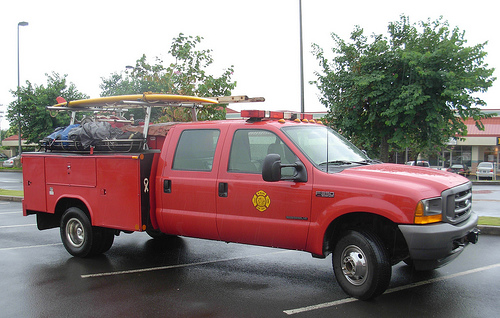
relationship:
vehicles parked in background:
[447, 156, 499, 178] [404, 153, 498, 174]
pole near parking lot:
[12, 16, 34, 143] [7, 172, 498, 317]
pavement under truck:
[1, 240, 499, 313] [12, 94, 486, 306]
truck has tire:
[12, 94, 486, 306] [328, 227, 399, 305]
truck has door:
[12, 94, 486, 306] [213, 124, 309, 246]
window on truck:
[171, 124, 221, 172] [12, 94, 486, 306]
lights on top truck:
[235, 106, 317, 124] [12, 94, 486, 306]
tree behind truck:
[316, 12, 493, 150] [12, 94, 486, 306]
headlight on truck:
[411, 191, 449, 227] [12, 94, 486, 306]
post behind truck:
[296, 0, 311, 112] [12, 94, 486, 306]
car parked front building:
[12, 94, 486, 306] [434, 99, 498, 164]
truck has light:
[12, 94, 486, 306] [411, 191, 449, 227]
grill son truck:
[42, 92, 261, 115] [12, 94, 486, 306]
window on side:
[171, 124, 221, 172] [22, 125, 339, 238]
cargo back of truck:
[36, 91, 168, 155] [12, 94, 486, 306]